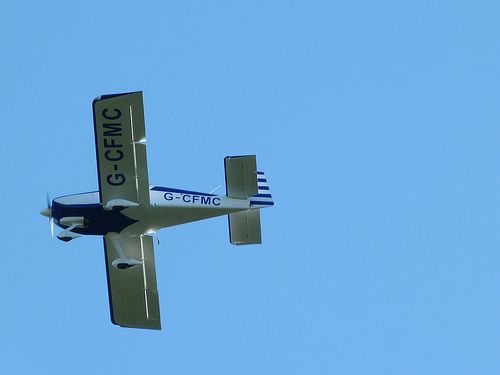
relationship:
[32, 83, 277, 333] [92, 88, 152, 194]
plane has wing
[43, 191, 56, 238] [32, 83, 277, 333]
propeller on front of plane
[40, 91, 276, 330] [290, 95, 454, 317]
plane in air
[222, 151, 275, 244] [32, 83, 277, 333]
tail of plane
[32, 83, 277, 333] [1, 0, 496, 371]
plane traveling on sky